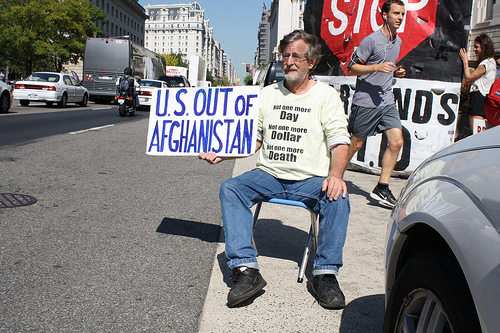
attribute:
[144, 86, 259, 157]
sign — white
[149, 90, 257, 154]
letters — blue